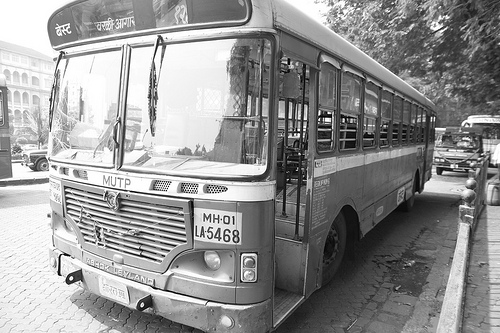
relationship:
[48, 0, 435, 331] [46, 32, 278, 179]
bus has a windshield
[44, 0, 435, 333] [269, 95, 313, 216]
bus door opened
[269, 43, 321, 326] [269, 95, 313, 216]
door door opened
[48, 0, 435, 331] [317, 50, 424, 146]
bus has windows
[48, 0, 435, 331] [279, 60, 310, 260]
bus windows are open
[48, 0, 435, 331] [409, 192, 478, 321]
bus next to sidewalk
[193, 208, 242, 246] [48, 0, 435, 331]
id number on bus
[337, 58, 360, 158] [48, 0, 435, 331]
window has bus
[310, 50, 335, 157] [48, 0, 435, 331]
window has bus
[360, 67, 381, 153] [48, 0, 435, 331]
window has bus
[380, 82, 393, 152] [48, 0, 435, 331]
window has bus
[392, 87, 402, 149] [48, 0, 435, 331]
window has bus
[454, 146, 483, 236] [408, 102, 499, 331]
fence between side walk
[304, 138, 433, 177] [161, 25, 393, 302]
stripe on side of bus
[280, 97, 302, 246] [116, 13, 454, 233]
poles inside of bus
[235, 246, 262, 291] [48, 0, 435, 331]
signal on bus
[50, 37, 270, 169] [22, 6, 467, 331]
windshield on bus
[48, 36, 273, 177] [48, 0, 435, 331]
windshield on bus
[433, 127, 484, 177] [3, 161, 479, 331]
van on street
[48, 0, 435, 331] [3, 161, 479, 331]
bus parked on street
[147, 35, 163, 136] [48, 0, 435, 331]
windshield wipers on bus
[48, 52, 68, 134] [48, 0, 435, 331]
windshield wiper on bus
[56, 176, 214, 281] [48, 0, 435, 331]
grill on front of bus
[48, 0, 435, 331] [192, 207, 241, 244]
bus has id number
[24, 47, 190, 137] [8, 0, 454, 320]
windshield wipers of bus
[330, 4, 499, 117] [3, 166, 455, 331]
trees hanging over road